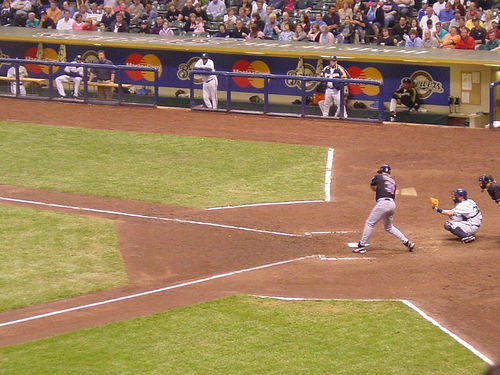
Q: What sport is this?
A: Baseball.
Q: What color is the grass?
A: Green.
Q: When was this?
A: Daytime.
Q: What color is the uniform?
A: White.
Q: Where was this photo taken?
A: At a baseball field.